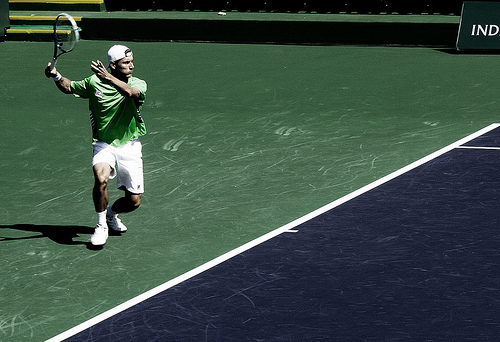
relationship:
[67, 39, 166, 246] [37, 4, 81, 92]
player holding racket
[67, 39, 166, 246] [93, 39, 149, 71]
player wearing cap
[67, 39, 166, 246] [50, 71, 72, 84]
player wearing wristband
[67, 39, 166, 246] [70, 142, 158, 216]
player wearing shorts